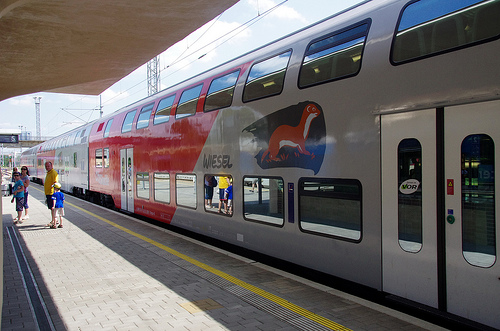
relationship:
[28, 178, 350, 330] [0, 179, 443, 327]
line on sidewalk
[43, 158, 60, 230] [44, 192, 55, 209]
man wearing shorts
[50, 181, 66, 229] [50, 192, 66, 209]
boy wearing shirt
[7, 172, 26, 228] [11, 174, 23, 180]
man wearing glasses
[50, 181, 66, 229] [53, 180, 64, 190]
boy wearing a hat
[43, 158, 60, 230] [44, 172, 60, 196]
man wearing a shirt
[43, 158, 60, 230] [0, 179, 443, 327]
man standing on sidewalk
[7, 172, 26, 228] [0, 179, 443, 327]
man standing on sidewalk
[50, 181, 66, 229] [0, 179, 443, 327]
boy on sidewalk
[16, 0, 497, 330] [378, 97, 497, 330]
train has doors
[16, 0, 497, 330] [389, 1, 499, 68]
train has window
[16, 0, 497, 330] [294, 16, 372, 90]
train has window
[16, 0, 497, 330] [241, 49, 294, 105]
train has window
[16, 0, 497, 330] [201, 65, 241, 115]
train has window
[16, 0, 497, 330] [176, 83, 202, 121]
train has window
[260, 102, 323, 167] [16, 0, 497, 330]
weasel painted on train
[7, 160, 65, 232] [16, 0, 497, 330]
family beside of train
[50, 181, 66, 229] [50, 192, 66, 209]
boy wearing a shirt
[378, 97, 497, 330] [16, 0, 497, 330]
doors are on train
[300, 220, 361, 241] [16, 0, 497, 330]
seats are in train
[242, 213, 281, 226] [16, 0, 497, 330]
seats are in train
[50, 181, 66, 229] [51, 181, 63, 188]
boy wearing a hat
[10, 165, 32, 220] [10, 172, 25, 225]
woman holding man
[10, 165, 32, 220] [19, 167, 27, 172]
woman wearing sunglasses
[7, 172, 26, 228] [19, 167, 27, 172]
man wearing sunglasses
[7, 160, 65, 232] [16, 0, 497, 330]
family beside train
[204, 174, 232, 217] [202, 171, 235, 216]
reflection on window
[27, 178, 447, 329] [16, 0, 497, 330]
shadow beside train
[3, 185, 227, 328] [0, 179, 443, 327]
sun reflected on sidewalk